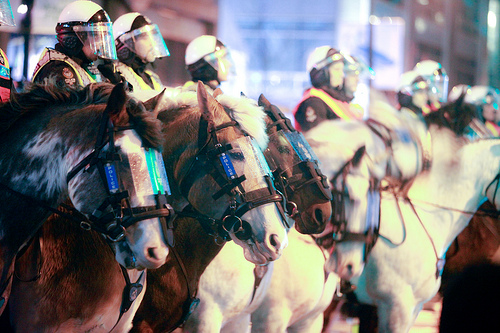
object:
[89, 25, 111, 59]
reflection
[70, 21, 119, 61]
face mask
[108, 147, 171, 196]
shield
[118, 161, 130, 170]
eye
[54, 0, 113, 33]
helmet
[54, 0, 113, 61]
head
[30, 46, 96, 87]
vest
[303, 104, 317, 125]
logo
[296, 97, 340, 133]
jacket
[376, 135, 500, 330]
horse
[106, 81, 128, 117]
right ear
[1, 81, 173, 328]
horse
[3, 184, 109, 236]
reigns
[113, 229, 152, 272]
mouth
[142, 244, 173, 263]
nose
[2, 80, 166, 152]
mane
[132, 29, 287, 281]
horse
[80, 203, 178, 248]
bit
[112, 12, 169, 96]
policeman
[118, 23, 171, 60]
face mask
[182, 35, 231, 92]
policeman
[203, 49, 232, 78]
face mask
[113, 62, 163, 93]
vest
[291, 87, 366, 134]
vest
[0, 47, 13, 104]
vest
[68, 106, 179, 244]
bridle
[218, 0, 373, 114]
building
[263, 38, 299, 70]
window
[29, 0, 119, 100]
people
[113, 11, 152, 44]
helmet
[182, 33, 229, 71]
helmet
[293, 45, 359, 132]
policeman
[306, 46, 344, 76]
helmet